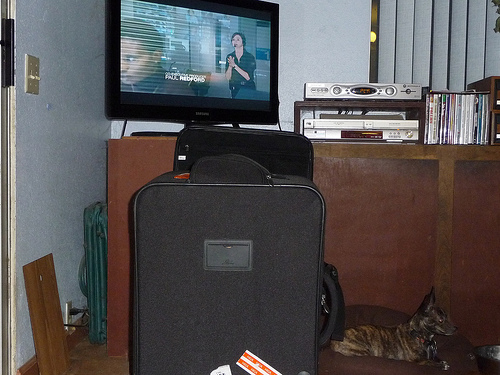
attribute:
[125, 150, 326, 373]
luggage — black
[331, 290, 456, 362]
dog — brown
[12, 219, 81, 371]
wood — balancing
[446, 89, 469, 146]
movie — one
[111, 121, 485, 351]
desk — one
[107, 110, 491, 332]
desk — one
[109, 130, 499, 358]
desk — one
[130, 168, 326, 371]
suitcase — black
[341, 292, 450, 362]
dog — brown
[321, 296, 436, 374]
bed — dog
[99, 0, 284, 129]
tv — illuminated, flatscreen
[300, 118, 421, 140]
player — DVD, silver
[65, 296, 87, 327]
plug — black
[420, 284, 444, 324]
ears — canine, pointy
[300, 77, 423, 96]
box — cable, silver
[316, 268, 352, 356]
handle — one, luggage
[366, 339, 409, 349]
fur — canine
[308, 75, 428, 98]
box — cable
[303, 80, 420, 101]
box — silver, cable 